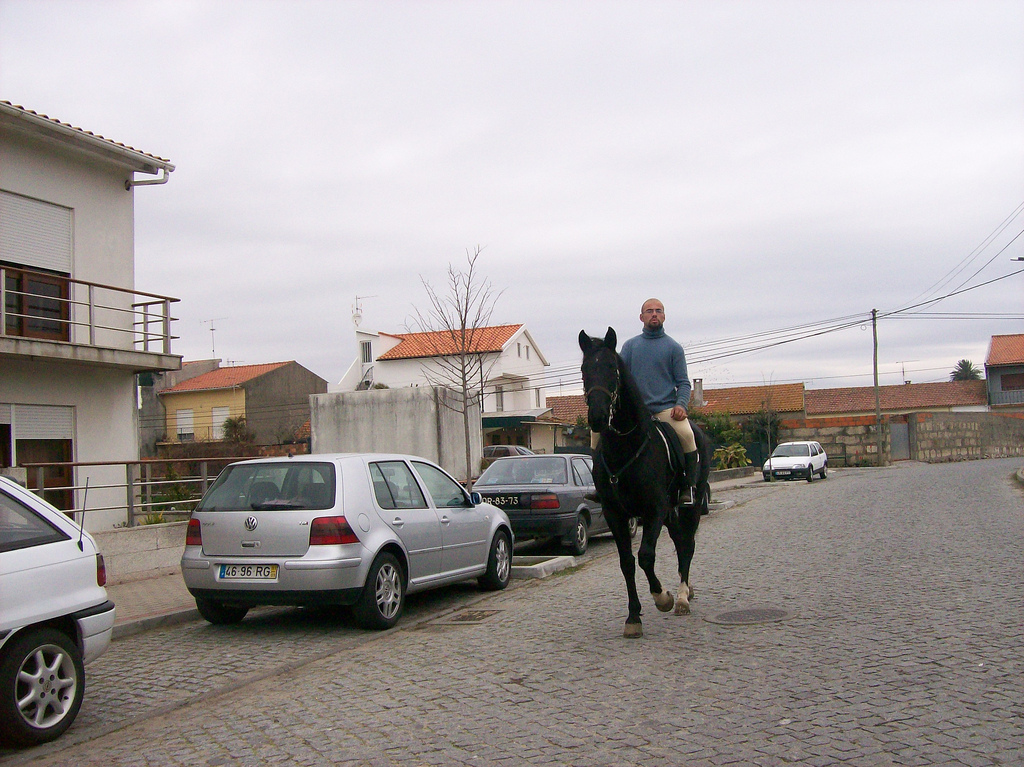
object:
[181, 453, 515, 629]
car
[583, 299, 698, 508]
man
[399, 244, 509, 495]
tree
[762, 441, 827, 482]
car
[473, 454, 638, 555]
car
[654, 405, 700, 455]
pants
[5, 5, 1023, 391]
sky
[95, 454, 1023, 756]
road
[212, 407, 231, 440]
window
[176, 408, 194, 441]
window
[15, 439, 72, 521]
window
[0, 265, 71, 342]
window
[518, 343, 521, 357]
window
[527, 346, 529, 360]
window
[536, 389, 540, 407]
window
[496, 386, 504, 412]
window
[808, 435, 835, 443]
stone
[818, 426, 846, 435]
stone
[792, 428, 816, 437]
stone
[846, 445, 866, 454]
stone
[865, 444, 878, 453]
stone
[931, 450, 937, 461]
stone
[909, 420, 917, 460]
stone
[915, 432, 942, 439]
stone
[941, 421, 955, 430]
stone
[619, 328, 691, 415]
shirt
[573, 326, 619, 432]
head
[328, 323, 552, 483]
building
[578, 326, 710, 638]
horse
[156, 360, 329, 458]
building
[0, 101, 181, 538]
building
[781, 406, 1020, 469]
wall